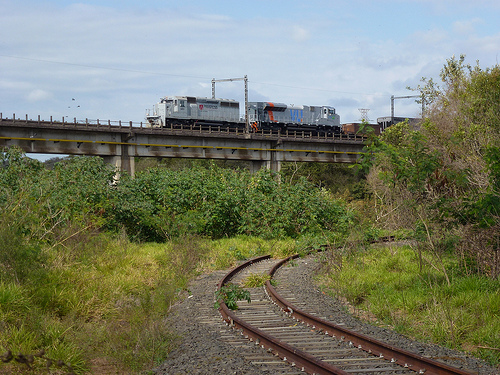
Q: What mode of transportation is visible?
A: Train.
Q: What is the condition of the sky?
A: Fairly cloudy.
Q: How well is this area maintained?
A: It's overgrown.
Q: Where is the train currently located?
A: On an elevated track.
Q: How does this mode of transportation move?
A: On tracks.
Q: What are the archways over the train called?
A: Trestles.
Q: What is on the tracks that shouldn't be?
A: Plant growth.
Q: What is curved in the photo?
A: Railroad tracks.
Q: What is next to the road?
A: Gravel.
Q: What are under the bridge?
A: Bushes.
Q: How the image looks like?
A: Good.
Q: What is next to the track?
A: Bushes.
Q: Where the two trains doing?
A: Riding across a railroad bridge.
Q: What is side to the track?
A: A half dead tree.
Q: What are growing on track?
A: Weeds.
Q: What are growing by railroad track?
A: Many shrubs and weeds.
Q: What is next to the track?
A: A grass and gravel patch.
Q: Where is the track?
A: On the ground.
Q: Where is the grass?
A: On the ground.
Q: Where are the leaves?
A: On the bushes.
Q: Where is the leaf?
A: On the bush.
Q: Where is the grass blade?
A: On the ground.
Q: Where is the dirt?
A: On the ground.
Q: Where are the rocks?
A: On the ground.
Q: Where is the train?
A: On the bridge.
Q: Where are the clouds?
A: In the sky.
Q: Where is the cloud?
A: In the sky.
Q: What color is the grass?
A: Green.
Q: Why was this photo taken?
A: To show a train.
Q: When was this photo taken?
A: In the daytime.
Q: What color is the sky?
A: Blue.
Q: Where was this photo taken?
A: By railroad tracks.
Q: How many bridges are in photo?
A: One.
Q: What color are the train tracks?
A: Brown.